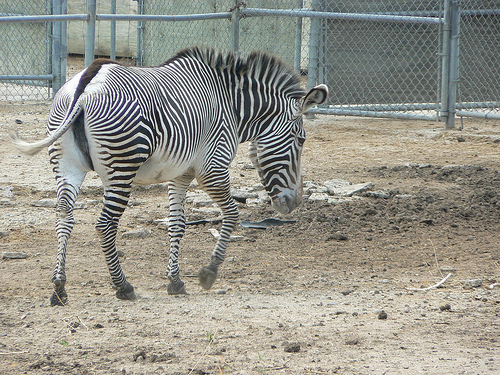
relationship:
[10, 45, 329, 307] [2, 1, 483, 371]
animal walking in pen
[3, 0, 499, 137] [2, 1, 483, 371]
fence lining pen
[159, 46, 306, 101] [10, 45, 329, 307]
mane growing on animal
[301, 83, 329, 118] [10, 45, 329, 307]
ear belonging to animal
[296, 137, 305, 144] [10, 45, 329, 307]
eye belonging to animal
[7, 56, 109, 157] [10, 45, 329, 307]
rear end belonging to animal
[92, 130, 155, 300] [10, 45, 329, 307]
hind leg belonging to animal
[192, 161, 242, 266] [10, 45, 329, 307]
leg belonging to animal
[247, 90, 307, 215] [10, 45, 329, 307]
head belonging to animal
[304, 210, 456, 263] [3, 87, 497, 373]
clumps of dirt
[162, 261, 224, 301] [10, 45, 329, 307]
hooves of animal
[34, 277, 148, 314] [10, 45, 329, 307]
hooves of animal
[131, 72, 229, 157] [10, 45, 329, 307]
stripes on animal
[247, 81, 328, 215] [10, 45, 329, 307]
head of animal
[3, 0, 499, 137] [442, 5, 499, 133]
fence with gate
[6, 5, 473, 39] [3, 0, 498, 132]
pipe in fence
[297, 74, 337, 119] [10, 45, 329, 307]
ear of animal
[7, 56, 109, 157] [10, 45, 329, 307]
rear end of animal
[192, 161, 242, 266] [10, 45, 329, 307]
leg of animal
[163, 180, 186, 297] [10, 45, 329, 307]
leg of animal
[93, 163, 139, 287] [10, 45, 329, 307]
leg of animal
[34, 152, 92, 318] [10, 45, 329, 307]
leg of animal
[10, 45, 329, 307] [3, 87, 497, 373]
animal in dirt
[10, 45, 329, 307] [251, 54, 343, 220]
animal with head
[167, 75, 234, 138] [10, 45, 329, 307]
stripes on animal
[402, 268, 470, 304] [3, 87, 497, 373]
stick in dirt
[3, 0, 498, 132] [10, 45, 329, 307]
fence behind animal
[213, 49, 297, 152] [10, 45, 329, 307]
neck on animal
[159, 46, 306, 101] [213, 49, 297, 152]
mane on neck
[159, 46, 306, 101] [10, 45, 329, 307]
mane on animal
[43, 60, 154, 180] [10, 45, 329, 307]
rear end on animal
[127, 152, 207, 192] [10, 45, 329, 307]
belly on animal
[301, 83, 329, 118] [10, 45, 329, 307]
ear on animal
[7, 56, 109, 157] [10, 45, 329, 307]
rear end on animal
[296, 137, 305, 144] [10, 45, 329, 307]
eye on animal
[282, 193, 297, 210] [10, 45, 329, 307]
mouth on animal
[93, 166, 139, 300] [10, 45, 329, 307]
leg on animal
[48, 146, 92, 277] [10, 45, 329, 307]
leg on animal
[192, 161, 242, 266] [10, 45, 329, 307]
leg on animal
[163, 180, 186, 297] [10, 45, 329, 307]
leg on animal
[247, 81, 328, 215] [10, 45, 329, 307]
head on animal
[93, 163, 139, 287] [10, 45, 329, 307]
leg on animal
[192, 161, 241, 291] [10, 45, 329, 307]
leg on animal